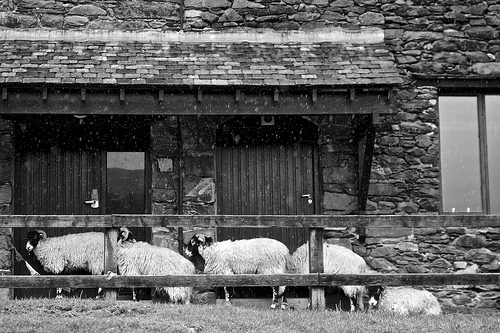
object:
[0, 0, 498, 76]
stone wall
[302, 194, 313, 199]
lock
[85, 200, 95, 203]
handle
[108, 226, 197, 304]
sheep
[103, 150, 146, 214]
window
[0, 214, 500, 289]
fence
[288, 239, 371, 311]
sheep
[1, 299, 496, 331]
grass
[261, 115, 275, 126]
object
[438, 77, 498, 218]
window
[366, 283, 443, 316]
sheep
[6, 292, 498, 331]
ground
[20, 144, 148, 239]
door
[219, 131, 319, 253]
door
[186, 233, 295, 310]
sheep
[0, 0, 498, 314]
building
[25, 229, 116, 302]
sheep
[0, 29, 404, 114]
roof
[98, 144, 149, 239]
doorway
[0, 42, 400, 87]
shingles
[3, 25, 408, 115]
awning